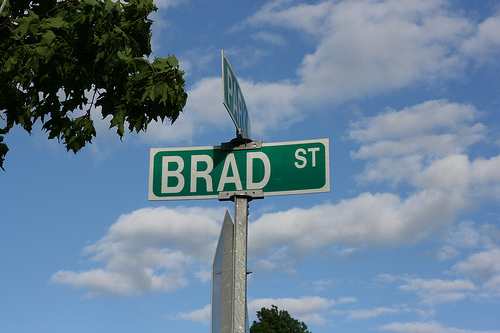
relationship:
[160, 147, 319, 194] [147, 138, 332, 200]
lettering on sign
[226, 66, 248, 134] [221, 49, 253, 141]
lettering on sign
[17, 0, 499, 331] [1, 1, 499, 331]
clouds in sky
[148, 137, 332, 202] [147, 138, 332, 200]
border on sign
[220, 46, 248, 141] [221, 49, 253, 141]
border on sign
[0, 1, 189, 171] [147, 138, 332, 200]
tree beyond sign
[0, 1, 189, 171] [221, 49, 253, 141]
tree beyond sign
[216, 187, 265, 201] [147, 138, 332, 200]
clasp on sign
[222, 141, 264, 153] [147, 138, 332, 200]
clasp on sign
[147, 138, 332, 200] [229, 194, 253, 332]
sign on pole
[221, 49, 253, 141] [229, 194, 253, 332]
sign on pole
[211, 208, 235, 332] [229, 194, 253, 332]
sign on pole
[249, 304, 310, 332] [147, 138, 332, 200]
tree under sign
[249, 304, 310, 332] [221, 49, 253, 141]
tree under sign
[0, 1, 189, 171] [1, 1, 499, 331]
tree in sky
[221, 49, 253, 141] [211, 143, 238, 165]
sign has a shadow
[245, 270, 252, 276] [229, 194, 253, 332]
bolt on pole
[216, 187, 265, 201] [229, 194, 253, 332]
clasp on pole